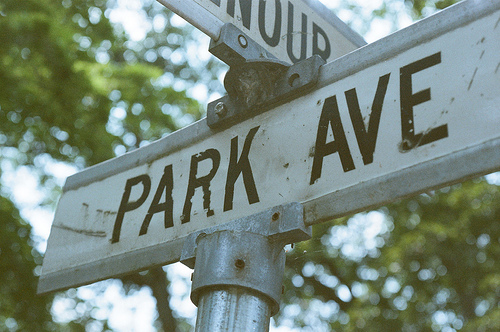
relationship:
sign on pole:
[26, 0, 500, 293] [169, 204, 339, 314]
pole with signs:
[109, 179, 350, 325] [30, 3, 466, 274]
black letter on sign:
[110, 51, 448, 249] [36, 42, 495, 284]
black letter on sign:
[110, 167, 151, 248] [26, 0, 500, 293]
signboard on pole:
[22, 99, 496, 240] [198, 288, 272, 330]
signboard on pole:
[180, 1, 362, 61] [198, 288, 272, 330]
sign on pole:
[26, 0, 500, 293] [177, 65, 327, 330]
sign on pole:
[26, 0, 500, 293] [179, 233, 275, 330]